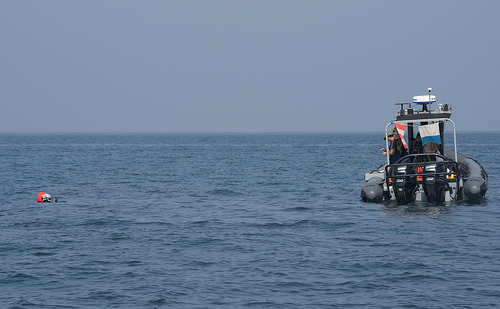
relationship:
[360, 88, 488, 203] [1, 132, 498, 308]
boat in ocean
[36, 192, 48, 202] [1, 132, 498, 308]
float in ocean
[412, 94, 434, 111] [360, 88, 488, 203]
antenna on top of boat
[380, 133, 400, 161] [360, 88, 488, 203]
man on boat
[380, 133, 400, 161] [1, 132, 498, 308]
man looking at ocean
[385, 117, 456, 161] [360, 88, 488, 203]
pole on boat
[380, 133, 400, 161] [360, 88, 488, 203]
man in boat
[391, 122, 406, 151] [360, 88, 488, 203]
flag on boat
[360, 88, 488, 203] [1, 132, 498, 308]
boat on ocean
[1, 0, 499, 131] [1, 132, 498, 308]
sky above ocean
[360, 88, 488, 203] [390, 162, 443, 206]
boat has motor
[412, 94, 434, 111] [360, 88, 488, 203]
antenna on boat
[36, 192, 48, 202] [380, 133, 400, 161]
float near man